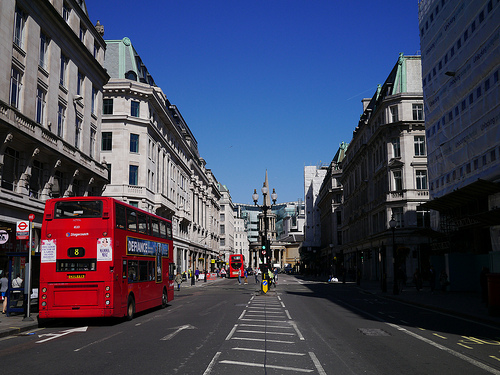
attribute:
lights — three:
[250, 179, 280, 204]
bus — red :
[228, 250, 246, 278]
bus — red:
[38, 198, 174, 320]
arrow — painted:
[161, 319, 202, 343]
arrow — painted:
[34, 327, 90, 349]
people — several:
[186, 248, 229, 297]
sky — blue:
[82, 0, 419, 205]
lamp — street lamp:
[257, 178, 273, 289]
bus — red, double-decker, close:
[31, 191, 184, 323]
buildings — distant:
[231, 187, 316, 277]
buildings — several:
[301, 0, 498, 337]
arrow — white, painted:
[155, 319, 200, 340]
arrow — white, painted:
[34, 324, 95, 342]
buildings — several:
[100, 42, 240, 277]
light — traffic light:
[238, 232, 283, 290]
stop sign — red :
[10, 216, 34, 237]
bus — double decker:
[227, 250, 245, 280]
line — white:
[306, 349, 324, 373]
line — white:
[202, 350, 221, 371]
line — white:
[77, 327, 120, 353]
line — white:
[441, 341, 476, 367]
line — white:
[280, 308, 294, 320]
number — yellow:
[72, 246, 80, 257]